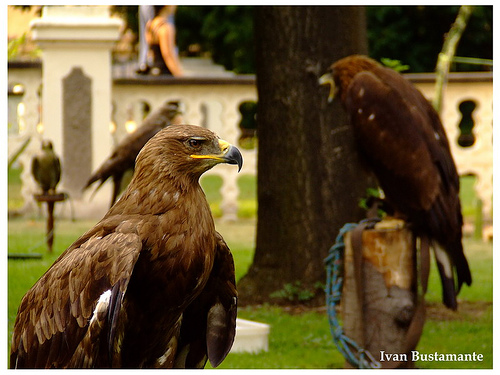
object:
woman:
[130, 0, 185, 77]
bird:
[96, 88, 199, 183]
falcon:
[43, 109, 259, 373]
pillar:
[32, 8, 132, 231]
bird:
[319, 44, 482, 289]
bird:
[89, 84, 185, 185]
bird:
[25, 131, 66, 190]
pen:
[10, 41, 493, 360]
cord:
[319, 219, 366, 360]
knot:
[320, 245, 338, 262]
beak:
[222, 142, 245, 171]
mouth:
[314, 73, 337, 103]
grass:
[9, 210, 499, 361]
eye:
[178, 133, 216, 152]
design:
[450, 88, 485, 156]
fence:
[218, 76, 498, 221]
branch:
[270, 281, 298, 315]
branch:
[303, 279, 316, 300]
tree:
[227, 0, 390, 305]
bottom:
[224, 188, 382, 314]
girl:
[132, 5, 178, 76]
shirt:
[148, 20, 172, 66]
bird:
[17, 109, 261, 373]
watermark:
[369, 340, 490, 370]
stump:
[335, 215, 436, 360]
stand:
[31, 188, 72, 243]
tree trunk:
[245, 20, 379, 314]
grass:
[272, 300, 332, 359]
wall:
[2, 0, 269, 210]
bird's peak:
[163, 121, 246, 176]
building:
[11, 39, 483, 229]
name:
[374, 344, 484, 372]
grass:
[264, 255, 482, 359]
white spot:
[73, 240, 163, 357]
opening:
[229, 97, 260, 158]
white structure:
[10, 7, 481, 202]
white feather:
[76, 286, 113, 332]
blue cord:
[323, 222, 389, 368]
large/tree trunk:
[242, 9, 368, 307]